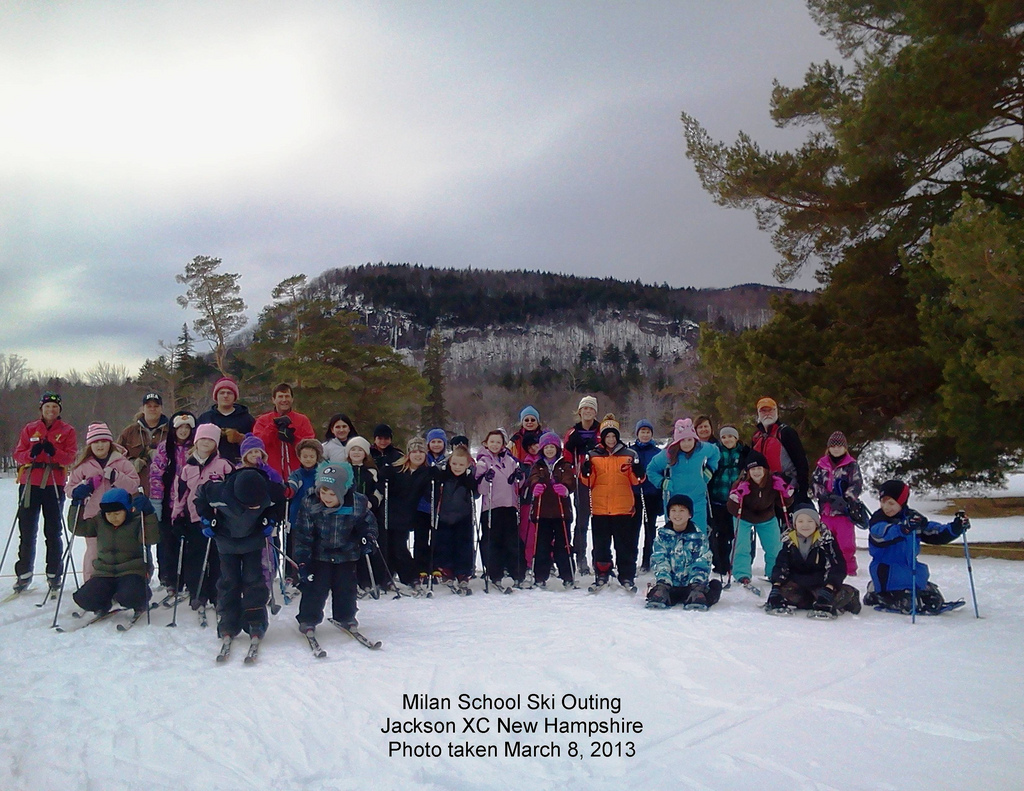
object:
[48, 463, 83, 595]
ski pole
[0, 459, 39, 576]
ski pole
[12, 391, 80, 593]
man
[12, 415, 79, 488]
jacket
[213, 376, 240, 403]
hat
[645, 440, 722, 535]
snow suit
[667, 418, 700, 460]
hat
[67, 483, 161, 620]
boy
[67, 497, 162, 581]
jacket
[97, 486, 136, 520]
hat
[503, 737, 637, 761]
date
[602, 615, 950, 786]
ski track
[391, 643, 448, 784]
ski track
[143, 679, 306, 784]
ski track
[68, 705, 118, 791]
ski track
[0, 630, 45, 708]
ski track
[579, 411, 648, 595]
person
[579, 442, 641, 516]
coat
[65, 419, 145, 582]
person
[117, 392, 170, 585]
person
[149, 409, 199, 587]
person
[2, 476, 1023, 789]
snow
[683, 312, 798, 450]
tree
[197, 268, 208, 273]
green leaves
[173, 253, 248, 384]
tree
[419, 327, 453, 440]
tree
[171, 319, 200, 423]
tree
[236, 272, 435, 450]
tree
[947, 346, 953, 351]
leaves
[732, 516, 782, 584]
snowpants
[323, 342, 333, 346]
leaves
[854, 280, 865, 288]
leaves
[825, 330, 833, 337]
leaves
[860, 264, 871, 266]
leaves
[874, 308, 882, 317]
leaves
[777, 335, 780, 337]
leaves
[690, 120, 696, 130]
leaves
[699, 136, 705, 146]
leaves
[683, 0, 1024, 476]
tree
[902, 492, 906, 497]
red stripe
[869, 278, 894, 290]
green leaves